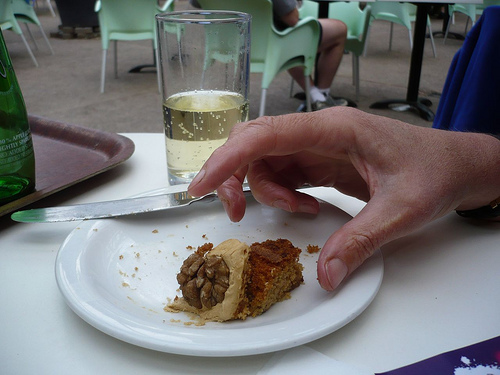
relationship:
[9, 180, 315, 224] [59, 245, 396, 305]
knife on plate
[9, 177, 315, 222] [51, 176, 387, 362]
knife on plate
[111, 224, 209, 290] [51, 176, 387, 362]
crubs on plate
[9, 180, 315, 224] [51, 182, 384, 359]
knife on plate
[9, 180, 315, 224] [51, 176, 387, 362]
knife on a plate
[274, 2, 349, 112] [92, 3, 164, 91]
person sitting in green chair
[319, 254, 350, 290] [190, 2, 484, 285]
nail of person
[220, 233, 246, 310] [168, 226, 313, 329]
gravy on food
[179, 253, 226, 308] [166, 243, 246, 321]
nuts on end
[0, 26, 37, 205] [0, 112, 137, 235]
bottle on tray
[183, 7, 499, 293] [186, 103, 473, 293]
person has hand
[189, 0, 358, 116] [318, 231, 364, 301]
person has nail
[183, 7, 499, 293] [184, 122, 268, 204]
person has finger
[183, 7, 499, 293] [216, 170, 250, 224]
person has finger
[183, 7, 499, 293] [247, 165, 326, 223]
person has finger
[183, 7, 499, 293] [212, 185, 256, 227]
person has finger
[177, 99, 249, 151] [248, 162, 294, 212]
person has finger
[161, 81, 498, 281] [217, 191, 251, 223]
person has nail